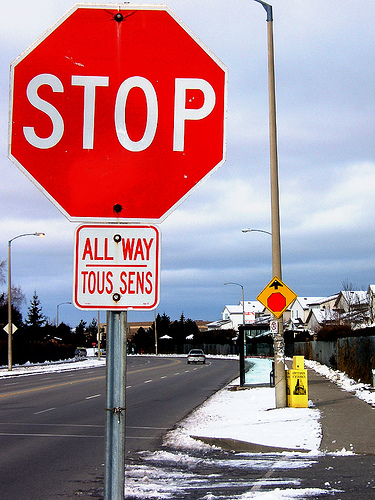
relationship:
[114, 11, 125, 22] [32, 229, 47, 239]
screw on steet light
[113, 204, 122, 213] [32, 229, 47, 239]
screw on steet light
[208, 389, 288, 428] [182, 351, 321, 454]
snow on grass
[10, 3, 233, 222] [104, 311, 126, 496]
stop sign on pole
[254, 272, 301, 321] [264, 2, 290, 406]
traffic sign on pole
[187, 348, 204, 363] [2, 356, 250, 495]
car on road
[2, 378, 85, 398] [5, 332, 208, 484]
yellow lines on road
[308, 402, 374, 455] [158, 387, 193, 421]
sidewalk next road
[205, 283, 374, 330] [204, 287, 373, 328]
white snow on houses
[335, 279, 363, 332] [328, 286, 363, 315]
tree front house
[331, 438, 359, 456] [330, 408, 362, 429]
snow on sidewalk